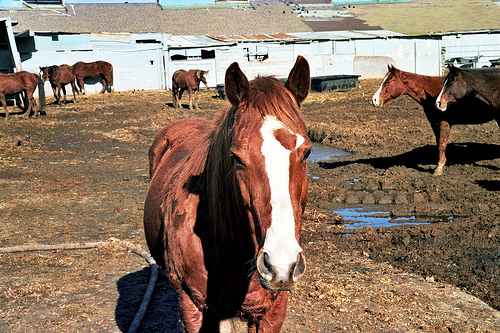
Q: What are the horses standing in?
A: Dirt.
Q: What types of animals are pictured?
A: Horses.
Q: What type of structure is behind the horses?
A: Stables.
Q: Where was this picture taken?
A: At a farm.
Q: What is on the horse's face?
A: A white spot.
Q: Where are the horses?
A: At a farm.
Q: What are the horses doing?
A: Standing in dirt.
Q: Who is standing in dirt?
A: The horses.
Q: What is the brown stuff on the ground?
A: Dirt.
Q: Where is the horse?
A: In the pasture.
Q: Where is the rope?
A: On the ground.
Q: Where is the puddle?
A: In the mud.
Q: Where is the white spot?
A: On the horse's nose.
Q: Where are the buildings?
A: Behind the horses.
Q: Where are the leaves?
A: On the ground.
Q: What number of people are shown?
A: Zero.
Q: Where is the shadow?
A: On the ground.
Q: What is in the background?
A: Buildings.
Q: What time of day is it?
A: Morning.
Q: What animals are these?
A: Horses.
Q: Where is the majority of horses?
A: By the buildings.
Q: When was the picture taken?
A: During the daytime.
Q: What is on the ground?
A: Dirt.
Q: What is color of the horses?
A: Brown.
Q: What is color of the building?
A: White.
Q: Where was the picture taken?
A: In a pastor.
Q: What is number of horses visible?
A: Seven.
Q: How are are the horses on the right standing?
A: Side by side.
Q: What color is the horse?
A: Brown.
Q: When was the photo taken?
A: Daytime.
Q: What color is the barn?
A: Grey.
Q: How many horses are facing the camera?
A: One.